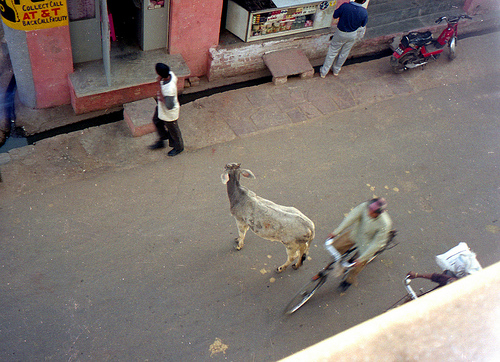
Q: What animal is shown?
A: Goat.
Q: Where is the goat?
A: In the street.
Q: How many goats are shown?
A: One.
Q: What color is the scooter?
A: Red.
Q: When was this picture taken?
A: Daytime.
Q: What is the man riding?
A: A bicycle.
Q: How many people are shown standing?
A: Two.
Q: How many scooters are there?
A: One.